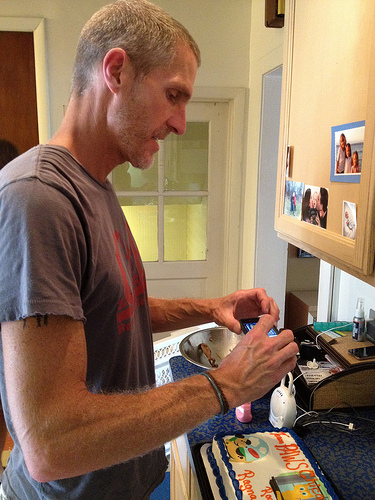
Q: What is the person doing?
A: Taking a picture.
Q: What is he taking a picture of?
A: A cake.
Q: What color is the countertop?
A: Blue.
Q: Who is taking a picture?
A: A man.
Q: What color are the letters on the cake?
A: Red.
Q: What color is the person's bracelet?
A: Black.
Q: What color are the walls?
A: White.